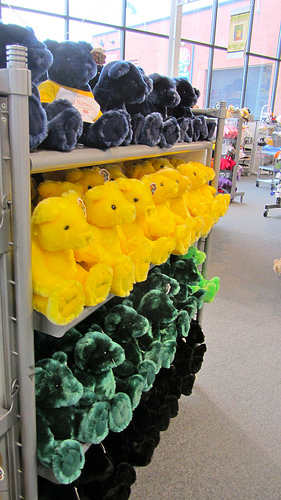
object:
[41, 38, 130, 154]
bear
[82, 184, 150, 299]
teddy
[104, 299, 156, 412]
stuffed animal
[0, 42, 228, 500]
shelf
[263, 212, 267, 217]
wheel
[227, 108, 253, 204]
rack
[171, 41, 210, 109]
window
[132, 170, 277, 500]
floor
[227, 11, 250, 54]
banner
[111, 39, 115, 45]
light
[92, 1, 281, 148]
building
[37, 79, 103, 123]
shirt